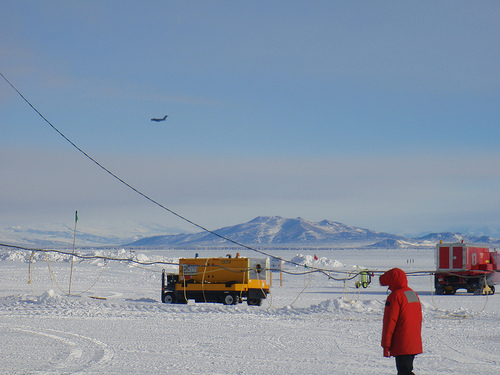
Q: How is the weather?
A: It is clear.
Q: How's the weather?
A: It is clear.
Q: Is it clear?
A: Yes, it is clear.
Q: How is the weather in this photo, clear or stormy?
A: It is clear.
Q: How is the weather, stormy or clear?
A: It is clear.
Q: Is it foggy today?
A: No, it is clear.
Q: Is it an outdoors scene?
A: Yes, it is outdoors.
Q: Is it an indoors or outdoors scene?
A: It is outdoors.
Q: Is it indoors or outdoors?
A: It is outdoors.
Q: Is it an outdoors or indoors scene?
A: It is outdoors.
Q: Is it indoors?
A: No, it is outdoors.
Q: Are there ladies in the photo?
A: No, there are no ladies.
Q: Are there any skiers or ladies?
A: No, there are no ladies or skiers.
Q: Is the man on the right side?
A: Yes, the man is on the right of the image.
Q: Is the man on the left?
A: No, the man is on the right of the image.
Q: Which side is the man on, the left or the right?
A: The man is on the right of the image.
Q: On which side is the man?
A: The man is on the right of the image.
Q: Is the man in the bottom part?
A: Yes, the man is in the bottom of the image.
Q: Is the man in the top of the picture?
A: No, the man is in the bottom of the image.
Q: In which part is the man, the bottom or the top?
A: The man is in the bottom of the image.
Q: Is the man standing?
A: Yes, the man is standing.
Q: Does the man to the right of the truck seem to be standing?
A: Yes, the man is standing.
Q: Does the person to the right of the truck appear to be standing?
A: Yes, the man is standing.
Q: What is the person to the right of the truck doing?
A: The man is standing.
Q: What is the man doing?
A: The man is standing.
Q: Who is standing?
A: The man is standing.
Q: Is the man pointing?
A: No, the man is standing.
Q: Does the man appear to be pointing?
A: No, the man is standing.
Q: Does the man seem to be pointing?
A: No, the man is standing.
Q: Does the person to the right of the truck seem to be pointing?
A: No, the man is standing.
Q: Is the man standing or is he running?
A: The man is standing.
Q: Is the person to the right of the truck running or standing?
A: The man is standing.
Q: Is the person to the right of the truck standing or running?
A: The man is standing.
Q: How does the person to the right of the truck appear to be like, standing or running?
A: The man is standing.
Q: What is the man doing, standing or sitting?
A: The man is standing.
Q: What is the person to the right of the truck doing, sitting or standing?
A: The man is standing.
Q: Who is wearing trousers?
A: The man is wearing trousers.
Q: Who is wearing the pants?
A: The man is wearing trousers.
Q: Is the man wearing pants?
A: Yes, the man is wearing pants.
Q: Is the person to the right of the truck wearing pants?
A: Yes, the man is wearing pants.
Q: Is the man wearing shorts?
A: No, the man is wearing pants.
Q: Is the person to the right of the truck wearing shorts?
A: No, the man is wearing pants.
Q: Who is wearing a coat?
A: The man is wearing a coat.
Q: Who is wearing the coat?
A: The man is wearing a coat.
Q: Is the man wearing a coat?
A: Yes, the man is wearing a coat.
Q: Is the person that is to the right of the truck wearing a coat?
A: Yes, the man is wearing a coat.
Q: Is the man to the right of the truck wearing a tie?
A: No, the man is wearing a coat.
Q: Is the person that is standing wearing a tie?
A: No, the man is wearing a coat.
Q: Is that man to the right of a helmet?
A: No, the man is to the right of the truck.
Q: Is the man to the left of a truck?
A: No, the man is to the right of a truck.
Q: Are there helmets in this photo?
A: No, there are no helmets.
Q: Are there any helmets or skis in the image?
A: No, there are no helmets or skis.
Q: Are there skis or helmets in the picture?
A: No, there are no helmets or skis.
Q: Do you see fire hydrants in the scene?
A: No, there are no fire hydrants.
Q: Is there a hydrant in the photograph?
A: No, there are no fire hydrants.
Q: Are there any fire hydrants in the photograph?
A: No, there are no fire hydrants.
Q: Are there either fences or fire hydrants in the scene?
A: No, there are no fire hydrants or fences.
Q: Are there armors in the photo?
A: No, there are no armors.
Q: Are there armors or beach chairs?
A: No, there are no armors or beach chairs.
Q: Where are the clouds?
A: The clouds are in the sky.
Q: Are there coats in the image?
A: Yes, there is a coat.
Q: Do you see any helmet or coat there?
A: Yes, there is a coat.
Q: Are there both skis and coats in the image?
A: No, there is a coat but no skis.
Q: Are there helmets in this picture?
A: No, there are no helmets.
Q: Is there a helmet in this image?
A: No, there are no helmets.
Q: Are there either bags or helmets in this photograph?
A: No, there are no helmets or bags.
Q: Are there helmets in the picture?
A: No, there are no helmets.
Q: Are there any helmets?
A: No, there are no helmets.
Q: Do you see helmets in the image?
A: No, there are no helmets.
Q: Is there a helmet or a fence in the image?
A: No, there are no helmets or fences.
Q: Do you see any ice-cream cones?
A: No, there are no ice-cream cones.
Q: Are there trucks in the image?
A: Yes, there is a truck.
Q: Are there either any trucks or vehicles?
A: Yes, there is a truck.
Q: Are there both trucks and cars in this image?
A: No, there is a truck but no cars.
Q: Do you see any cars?
A: No, there are no cars.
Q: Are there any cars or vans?
A: No, there are no cars or vans.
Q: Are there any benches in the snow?
A: No, there is a truck in the snow.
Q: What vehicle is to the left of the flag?
A: The vehicle is a truck.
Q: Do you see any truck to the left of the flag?
A: Yes, there is a truck to the left of the flag.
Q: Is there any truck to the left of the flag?
A: Yes, there is a truck to the left of the flag.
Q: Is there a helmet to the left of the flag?
A: No, there is a truck to the left of the flag.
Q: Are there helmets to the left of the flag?
A: No, there is a truck to the left of the flag.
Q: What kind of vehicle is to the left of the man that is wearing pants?
A: The vehicle is a truck.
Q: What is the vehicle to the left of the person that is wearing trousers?
A: The vehicle is a truck.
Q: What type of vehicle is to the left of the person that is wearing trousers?
A: The vehicle is a truck.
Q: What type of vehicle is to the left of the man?
A: The vehicle is a truck.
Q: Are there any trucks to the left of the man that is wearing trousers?
A: Yes, there is a truck to the left of the man.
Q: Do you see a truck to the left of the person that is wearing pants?
A: Yes, there is a truck to the left of the man.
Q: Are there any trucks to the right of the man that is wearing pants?
A: No, the truck is to the left of the man.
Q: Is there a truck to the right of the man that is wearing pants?
A: No, the truck is to the left of the man.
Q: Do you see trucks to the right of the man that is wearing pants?
A: No, the truck is to the left of the man.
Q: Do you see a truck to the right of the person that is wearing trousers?
A: No, the truck is to the left of the man.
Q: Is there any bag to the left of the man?
A: No, there is a truck to the left of the man.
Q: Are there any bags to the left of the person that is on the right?
A: No, there is a truck to the left of the man.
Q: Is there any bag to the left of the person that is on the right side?
A: No, there is a truck to the left of the man.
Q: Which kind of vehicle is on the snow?
A: The vehicle is a truck.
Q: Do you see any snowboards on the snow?
A: No, there is a truck on the snow.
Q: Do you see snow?
A: Yes, there is snow.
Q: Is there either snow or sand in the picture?
A: Yes, there is snow.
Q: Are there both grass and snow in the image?
A: No, there is snow but no grass.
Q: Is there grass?
A: No, there is no grass.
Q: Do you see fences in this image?
A: No, there are no fences.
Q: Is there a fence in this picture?
A: No, there are no fences.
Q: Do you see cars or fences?
A: No, there are no fences or cars.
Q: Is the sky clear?
A: Yes, the sky is clear.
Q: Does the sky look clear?
A: Yes, the sky is clear.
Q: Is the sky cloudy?
A: No, the sky is clear.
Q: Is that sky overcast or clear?
A: The sky is clear.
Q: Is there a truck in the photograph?
A: Yes, there is a truck.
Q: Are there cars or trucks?
A: Yes, there is a truck.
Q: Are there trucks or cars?
A: Yes, there is a truck.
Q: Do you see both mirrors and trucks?
A: No, there is a truck but no mirrors.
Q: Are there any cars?
A: No, there are no cars.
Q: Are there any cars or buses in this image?
A: No, there are no cars or buses.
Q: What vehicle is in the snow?
A: The vehicle is a truck.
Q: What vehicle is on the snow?
A: The vehicle is a truck.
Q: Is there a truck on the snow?
A: Yes, there is a truck on the snow.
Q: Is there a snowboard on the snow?
A: No, there is a truck on the snow.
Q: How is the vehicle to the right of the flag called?
A: The vehicle is a truck.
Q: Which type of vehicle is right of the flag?
A: The vehicle is a truck.